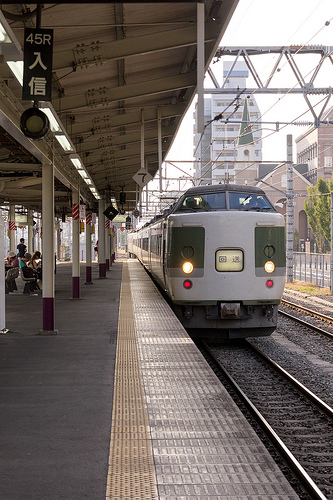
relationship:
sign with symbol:
[22, 28, 53, 99] [29, 52, 46, 70]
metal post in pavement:
[39, 154, 59, 338] [114, 267, 139, 281]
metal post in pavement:
[95, 199, 107, 280] [24, 338, 102, 456]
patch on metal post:
[71, 202, 80, 220] [71, 182, 80, 300]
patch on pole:
[84, 210, 93, 224] [85, 210, 93, 284]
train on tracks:
[128, 185, 288, 342] [205, 321, 323, 442]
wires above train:
[144, 49, 328, 182] [100, 165, 310, 357]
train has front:
[128, 185, 288, 342] [169, 183, 286, 341]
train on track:
[128, 185, 288, 339] [171, 301, 329, 391]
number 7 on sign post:
[136, 170, 148, 184] [127, 108, 153, 188]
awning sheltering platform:
[3, 6, 235, 203] [0, 257, 299, 497]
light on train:
[160, 236, 293, 293] [135, 167, 276, 298]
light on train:
[181, 243, 277, 291] [128, 185, 288, 339]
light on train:
[181, 243, 277, 291] [127, 180, 297, 331]